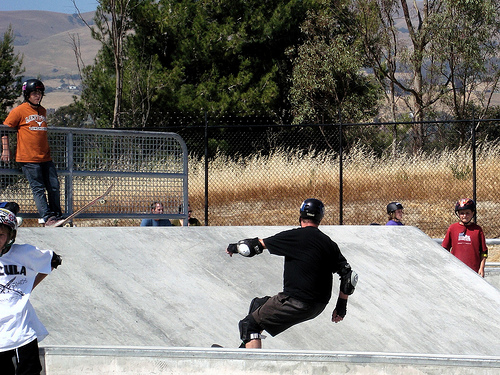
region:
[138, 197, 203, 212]
NON SKATERS DO NOT WEAR HELMETS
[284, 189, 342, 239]
ALL SKATERS WEAR HELMETS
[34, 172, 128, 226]
SKATE BOARD IS ON AN ANGLE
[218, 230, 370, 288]
SKATE BOARDER IS WEARING ELBOW PADS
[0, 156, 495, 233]
GRASS AREA IN MIDDLE OF PICTURE IS BROWN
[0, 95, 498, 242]
FENCE LOCATED IN THE BACKGROUND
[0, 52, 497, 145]
TREES IN THE BACK ARE GREEN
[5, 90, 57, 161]
SKATE BOARDER IS WEARING ORANGE SHIRT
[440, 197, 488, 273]
BOY TO RIGHT MIDDLE IS WEARING RED SHIRT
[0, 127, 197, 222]
METAL FENCE AT TOP OF SKATE RAMP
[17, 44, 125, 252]
man in orange shirt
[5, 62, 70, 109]
man wearing blue helmet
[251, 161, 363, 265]
man wearing black helmet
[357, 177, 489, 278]
two boys watching in photo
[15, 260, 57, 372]
person wearing a white shirt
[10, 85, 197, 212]
person leaning against a fence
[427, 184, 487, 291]
boy wearing red shirt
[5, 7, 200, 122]
mountains in background of photo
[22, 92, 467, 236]
black metal fence in background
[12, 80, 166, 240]
man standing on one end of skateboard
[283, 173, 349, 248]
black helmet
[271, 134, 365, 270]
black helmet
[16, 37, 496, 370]
a skatepark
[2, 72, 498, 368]
people gathered around a skating ramp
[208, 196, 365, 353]
a man is using the skate ramp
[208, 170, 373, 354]
the man on the skateboard is wearing black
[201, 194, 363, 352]
the skateboarder is wearing protective gear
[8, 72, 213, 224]
another skateboarder waits at the top of the ramp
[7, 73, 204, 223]
the skateboarder in the orange shirt leans on a railing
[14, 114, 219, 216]
a metal railing is at the top of the ramp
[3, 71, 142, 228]
the boy in orange holds a skateboard with his foot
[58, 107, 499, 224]
a metal fence surrounds the area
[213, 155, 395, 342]
a skateboarder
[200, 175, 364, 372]
a skateboarder about to perform a trick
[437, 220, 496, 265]
a kid wearing a red shirt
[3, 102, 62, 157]
a boy wearing an orange shirt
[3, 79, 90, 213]
a boy leaning on a metal fence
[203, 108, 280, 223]
a black metal fence with barbed wires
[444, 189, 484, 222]
boy wearing a black an red helmet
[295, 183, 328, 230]
man wearing a black helmet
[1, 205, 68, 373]
person holding their back with their hands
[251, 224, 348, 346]
manwearing black shirt and shorts